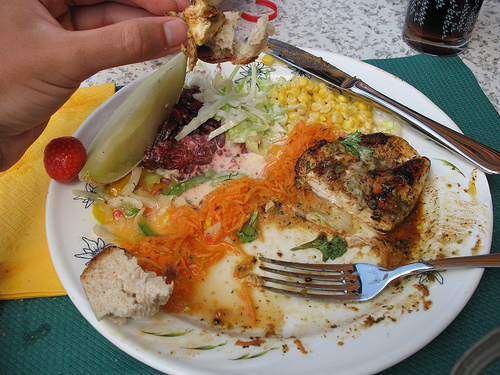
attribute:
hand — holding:
[21, 6, 205, 138]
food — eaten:
[82, 59, 436, 373]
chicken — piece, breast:
[312, 166, 432, 230]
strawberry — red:
[56, 145, 88, 183]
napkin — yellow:
[14, 205, 49, 291]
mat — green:
[429, 66, 469, 103]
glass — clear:
[384, 12, 481, 71]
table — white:
[323, 15, 385, 63]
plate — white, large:
[46, 209, 92, 264]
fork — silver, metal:
[258, 220, 478, 331]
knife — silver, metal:
[262, 33, 466, 119]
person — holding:
[1, 10, 270, 177]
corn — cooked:
[288, 78, 375, 132]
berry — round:
[49, 131, 93, 187]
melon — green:
[97, 52, 205, 181]